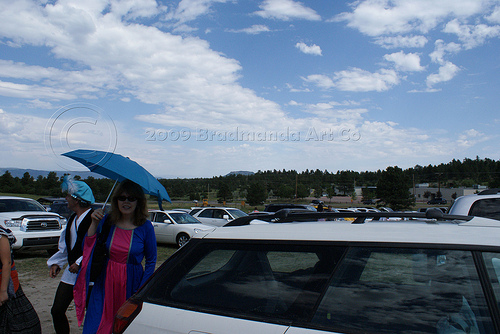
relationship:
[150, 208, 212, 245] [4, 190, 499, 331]
coupe in parking lot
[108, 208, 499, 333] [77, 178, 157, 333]
vehicle next to woman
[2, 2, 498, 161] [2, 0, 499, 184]
sky with clouds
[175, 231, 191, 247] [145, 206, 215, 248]
tire of car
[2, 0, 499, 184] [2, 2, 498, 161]
clouds in sky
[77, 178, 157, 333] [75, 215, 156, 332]
woman wearing dress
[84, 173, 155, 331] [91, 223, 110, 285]
woman carrying black purse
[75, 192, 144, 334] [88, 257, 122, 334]
girl in a dress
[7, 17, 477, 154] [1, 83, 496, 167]
clouds in sky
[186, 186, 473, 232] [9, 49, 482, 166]
people in background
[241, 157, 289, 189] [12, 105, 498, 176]
mountains in background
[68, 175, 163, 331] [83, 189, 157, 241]
woman wearing sun glasses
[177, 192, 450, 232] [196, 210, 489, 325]
rack on roof of car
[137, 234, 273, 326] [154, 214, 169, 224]
part of a car window